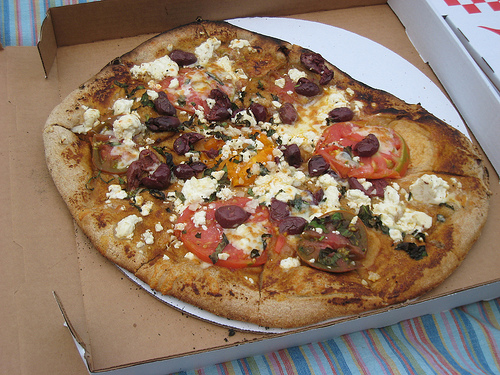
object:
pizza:
[42, 17, 490, 330]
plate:
[85, 17, 475, 334]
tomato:
[314, 123, 408, 182]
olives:
[215, 205, 252, 228]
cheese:
[412, 174, 449, 202]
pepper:
[219, 128, 274, 186]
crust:
[42, 68, 76, 202]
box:
[0, 2, 498, 374]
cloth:
[1, 1, 500, 373]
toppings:
[177, 195, 286, 267]